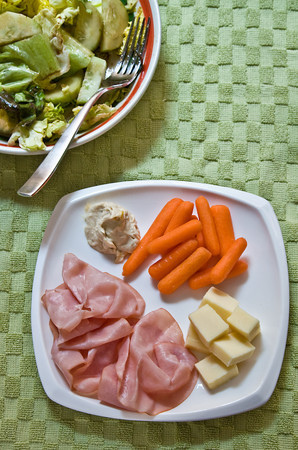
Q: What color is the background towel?
A: Green.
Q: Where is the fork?
A: In the salad bowl.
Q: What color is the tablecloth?
A: Green.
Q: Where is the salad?
A: In the bowl.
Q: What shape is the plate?
A: Square.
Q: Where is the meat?
A: In the corner.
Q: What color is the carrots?
A: Orange.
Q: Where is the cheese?
A: By the meat.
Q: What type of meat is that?
A: Ham.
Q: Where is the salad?
A: In the corner.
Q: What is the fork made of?
A: Metal.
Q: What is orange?
A: Carrots.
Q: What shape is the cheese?
A: Square.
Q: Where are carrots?
A: On a plate.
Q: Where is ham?
A: On plate.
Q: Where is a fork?
A: In a bowl.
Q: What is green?
A: Lettuce.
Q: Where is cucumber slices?
A: In a bowl.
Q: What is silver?
A: Fork.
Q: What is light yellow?
A: The cheese.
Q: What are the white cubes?
A: Cheese.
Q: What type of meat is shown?
A: Deli.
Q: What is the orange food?
A: Carrots.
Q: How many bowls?
A: 1.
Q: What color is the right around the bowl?
A: Brown.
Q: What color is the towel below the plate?
A: Green.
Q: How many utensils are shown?
A: 1.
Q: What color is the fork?
A: Silver.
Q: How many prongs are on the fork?
A: 4.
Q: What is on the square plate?
A: Ham, cheese, carrots, hummus.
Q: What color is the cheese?
A: White.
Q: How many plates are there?
A: Two.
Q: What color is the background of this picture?
A: Green.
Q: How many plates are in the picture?
A: 2.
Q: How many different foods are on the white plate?
A: 4.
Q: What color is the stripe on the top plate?
A: Red.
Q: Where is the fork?
A: On the top plate.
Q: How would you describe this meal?
A: Healthy.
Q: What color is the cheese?
A: White.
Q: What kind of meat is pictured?
A: Ham.